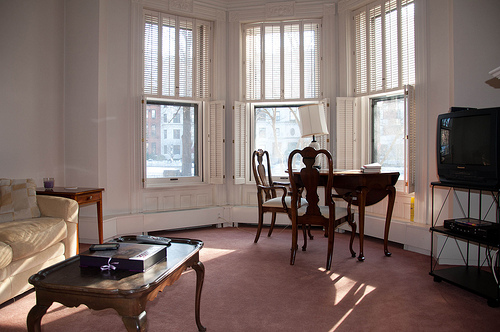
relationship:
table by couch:
[42, 216, 206, 330] [8, 152, 108, 261]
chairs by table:
[249, 137, 362, 234] [42, 216, 206, 330]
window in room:
[129, 7, 437, 209] [6, 2, 497, 297]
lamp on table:
[288, 77, 335, 173] [264, 154, 403, 215]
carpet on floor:
[211, 224, 299, 280] [189, 208, 317, 286]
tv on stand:
[419, 102, 492, 191] [425, 178, 498, 298]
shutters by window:
[147, 14, 401, 101] [129, 7, 437, 209]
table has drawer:
[42, 216, 206, 330] [71, 189, 104, 212]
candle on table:
[37, 166, 79, 206] [39, 177, 125, 237]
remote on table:
[132, 232, 181, 249] [42, 216, 206, 330]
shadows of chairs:
[273, 249, 367, 330] [249, 137, 362, 234]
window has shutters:
[129, 7, 437, 209] [147, 14, 401, 101]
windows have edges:
[129, 7, 437, 209] [133, 23, 172, 205]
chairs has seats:
[249, 137, 362, 234] [265, 193, 338, 219]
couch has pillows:
[8, 152, 108, 261] [0, 173, 60, 232]